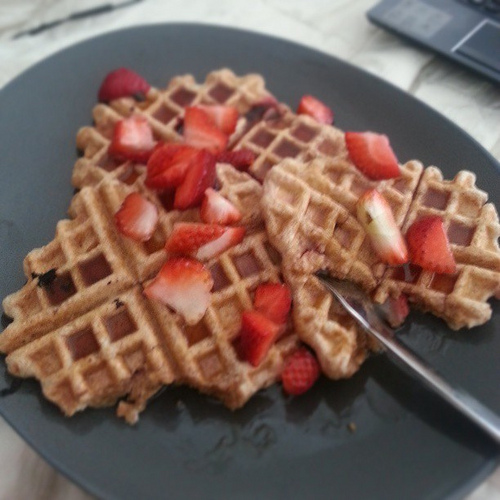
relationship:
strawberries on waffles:
[112, 105, 249, 302] [13, 66, 474, 452]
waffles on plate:
[13, 66, 474, 452] [0, 25, 472, 498]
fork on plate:
[320, 273, 497, 463] [0, 25, 472, 498]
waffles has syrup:
[13, 66, 474, 452] [159, 408, 357, 471]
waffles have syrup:
[13, 66, 474, 452] [159, 408, 357, 471]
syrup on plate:
[159, 408, 357, 471] [0, 25, 472, 498]